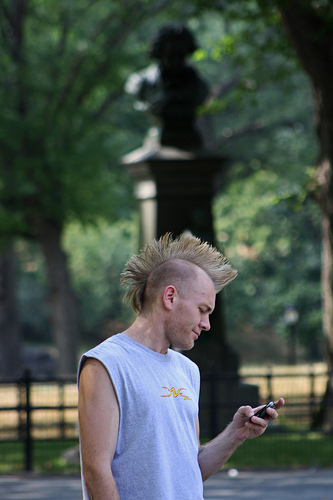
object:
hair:
[118, 229, 236, 316]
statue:
[118, 13, 245, 376]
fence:
[0, 358, 332, 476]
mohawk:
[120, 229, 238, 314]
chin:
[175, 333, 194, 350]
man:
[73, 209, 270, 367]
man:
[77, 230, 284, 500]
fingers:
[240, 405, 253, 420]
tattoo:
[197, 448, 204, 456]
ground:
[251, 74, 299, 130]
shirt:
[79, 330, 203, 499]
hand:
[231, 396, 286, 443]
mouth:
[191, 328, 200, 341]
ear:
[162, 285, 177, 310]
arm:
[192, 419, 234, 483]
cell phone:
[248, 401, 275, 424]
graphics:
[160, 386, 192, 401]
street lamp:
[282, 304, 300, 365]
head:
[137, 257, 215, 350]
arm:
[75, 340, 127, 498]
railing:
[1, 377, 332, 482]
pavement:
[1, 466, 332, 498]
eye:
[198, 305, 207, 314]